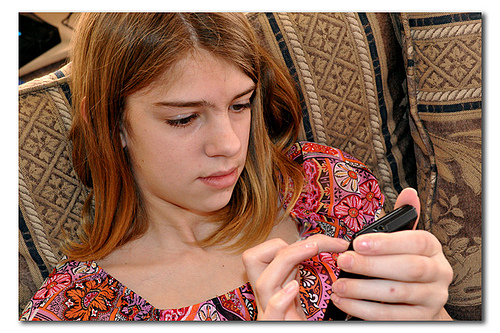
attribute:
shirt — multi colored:
[27, 153, 369, 319]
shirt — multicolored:
[22, 132, 408, 329]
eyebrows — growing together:
[141, 80, 306, 127]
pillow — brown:
[18, 12, 416, 319]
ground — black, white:
[403, 119, 427, 136]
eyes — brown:
[150, 84, 286, 137]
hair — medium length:
[19, 15, 484, 320]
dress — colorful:
[20, 140, 382, 321]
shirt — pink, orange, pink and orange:
[20, 140, 385, 321]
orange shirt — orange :
[20, 139, 373, 329]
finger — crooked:
[238, 230, 291, 307]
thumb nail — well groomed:
[397, 184, 419, 197]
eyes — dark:
[136, 80, 259, 132]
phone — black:
[320, 190, 425, 325]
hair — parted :
[69, 23, 297, 246]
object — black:
[320, 197, 426, 319]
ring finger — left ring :
[334, 277, 433, 302]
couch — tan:
[21, 14, 483, 322]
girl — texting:
[20, 17, 456, 318]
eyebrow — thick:
[230, 83, 260, 103]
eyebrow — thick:
[153, 96, 209, 108]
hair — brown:
[54, 10, 304, 267]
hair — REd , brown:
[52, 14, 310, 249]